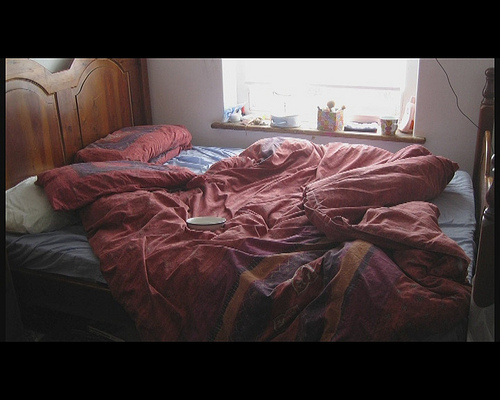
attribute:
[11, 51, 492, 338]
bed — unmade, undone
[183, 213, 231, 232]
bowl — white, round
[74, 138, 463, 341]
duvet — pink, rumpled, burgundy, messed up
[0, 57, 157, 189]
headboard — wood, dark, wooden, brown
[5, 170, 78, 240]
pillow — white, cloth, three, fluffy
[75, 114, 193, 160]
pillow — burgundy, pink, purple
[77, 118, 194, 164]
case — black, red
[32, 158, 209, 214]
pillow — burgundy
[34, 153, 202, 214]
case — red, black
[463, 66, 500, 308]
frame — wooden, brown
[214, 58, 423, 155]
window — uncovered, large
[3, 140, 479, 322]
sheets — white, blue, crumpled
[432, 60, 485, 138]
wire — black, hanging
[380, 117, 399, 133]
mug — little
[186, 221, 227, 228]
rim — blue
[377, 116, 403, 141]
cup — multi-colored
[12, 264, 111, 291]
line — white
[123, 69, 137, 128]
stripe — tan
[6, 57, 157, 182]
mahogany — deep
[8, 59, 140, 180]
pattern — intricate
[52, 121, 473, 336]
bedspread — large, red, brown